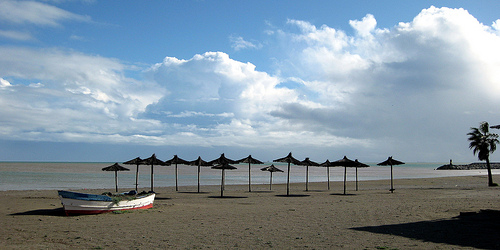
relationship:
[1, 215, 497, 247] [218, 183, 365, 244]
beach sand with footprints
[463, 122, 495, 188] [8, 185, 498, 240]
palm tree growing in sand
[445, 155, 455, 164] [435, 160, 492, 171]
lighthouse on flat land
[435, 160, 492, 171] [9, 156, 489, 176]
flat land jutting into ocean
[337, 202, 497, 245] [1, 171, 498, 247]
shadow pointing across beach sand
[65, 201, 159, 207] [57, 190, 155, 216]
stripes painted across boat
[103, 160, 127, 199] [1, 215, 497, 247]
large umbrella in beach sand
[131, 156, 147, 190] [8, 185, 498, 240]
large umbrella in sand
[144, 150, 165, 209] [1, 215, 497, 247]
large umbrella in beach sand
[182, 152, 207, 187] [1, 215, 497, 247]
large umbrella in beach sand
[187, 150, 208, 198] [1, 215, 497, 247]
large umbrella in beach sand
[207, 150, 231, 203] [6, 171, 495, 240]
large umbrella in sand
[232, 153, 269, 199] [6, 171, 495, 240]
large umbrella in sand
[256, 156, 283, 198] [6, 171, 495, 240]
large umbrella in sand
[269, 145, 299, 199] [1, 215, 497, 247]
large umbrella in beach sand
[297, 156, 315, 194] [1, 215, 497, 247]
large umbrella in beach sand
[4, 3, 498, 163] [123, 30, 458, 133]
blue sky with white clouds